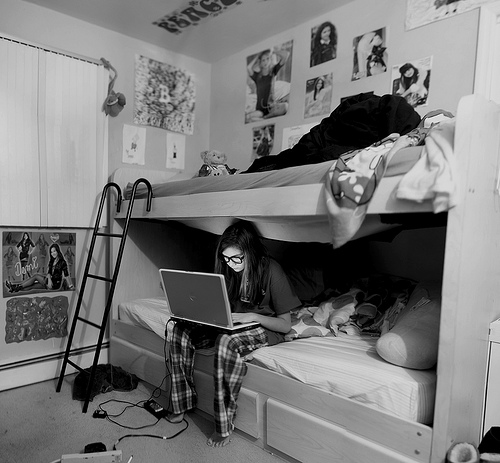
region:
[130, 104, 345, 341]
VIEW IN A VBEDROOKM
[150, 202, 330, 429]
ladt is using the laptop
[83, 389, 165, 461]
the cbls ar on th floor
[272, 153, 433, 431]
the beds are double deckerd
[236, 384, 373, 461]
the beds are ,made of wood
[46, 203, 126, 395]
the lader is black in color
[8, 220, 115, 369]
the pictures are on the frame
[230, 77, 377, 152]
clothes are scaterd on the bed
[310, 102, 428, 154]
the cloth is v]black in color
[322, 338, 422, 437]
the bedcovers are white in color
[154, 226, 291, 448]
a girl is using a computer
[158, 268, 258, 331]
a laptop computer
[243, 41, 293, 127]
a poster on a wall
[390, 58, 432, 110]
a poster on a wall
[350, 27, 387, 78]
a poster on a wall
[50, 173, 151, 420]
a ladder for a bunk bed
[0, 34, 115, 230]
white blinds cover a window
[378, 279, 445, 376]
a pillow on a bed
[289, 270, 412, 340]
blankets on a bed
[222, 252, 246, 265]
glasses on a girl's face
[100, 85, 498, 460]
A bunk bed in a dorm room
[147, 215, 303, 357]
Girl working on her laptop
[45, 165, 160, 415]
A black ladder leading to top bed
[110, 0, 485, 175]
Many posters on the walls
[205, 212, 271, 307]
Girl has long hair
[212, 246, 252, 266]
A pair of glasses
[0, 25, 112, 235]
Vertical binds are closed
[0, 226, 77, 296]
Women are on a poster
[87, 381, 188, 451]
Black electric wires on the floor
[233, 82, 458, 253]
Blankets on a bed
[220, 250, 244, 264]
a girl's black eyeglasses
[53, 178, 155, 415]
a black ladder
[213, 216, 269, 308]
a girl's long black hair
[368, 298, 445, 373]
part of a pillow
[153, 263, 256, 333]
part of a laptop computer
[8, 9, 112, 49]
part of a white wall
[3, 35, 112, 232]
white window blinds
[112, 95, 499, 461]
a large bunk bed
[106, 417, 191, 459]
a long black cord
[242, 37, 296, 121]
a large wall poster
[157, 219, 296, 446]
young woman with glasses using laptop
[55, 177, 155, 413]
metal ladder for bunk bed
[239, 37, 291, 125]
poster featuring a woman in a leotard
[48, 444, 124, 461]
power strip with two appliances plugged in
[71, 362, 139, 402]
crumpled towel on floor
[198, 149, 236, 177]
teddy bear perched on upper bunk of bunk bed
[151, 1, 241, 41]
poster with the word "peace" on it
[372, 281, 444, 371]
pillow lying on bed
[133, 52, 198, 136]
poster featuring the letter B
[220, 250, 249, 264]
dark, thick-rimmed glasses being worn